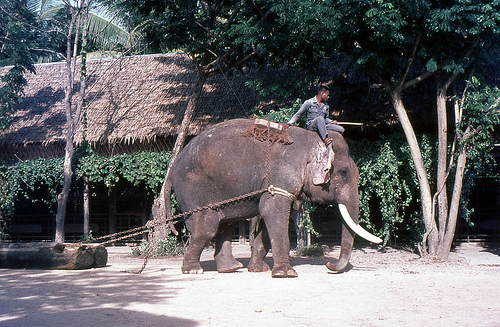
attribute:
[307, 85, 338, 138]
man — sitting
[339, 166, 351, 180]
eyes — open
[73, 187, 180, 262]
chain — Brown 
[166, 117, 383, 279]
elephant — walking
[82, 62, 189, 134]
roof — thatched 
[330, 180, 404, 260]
tusks — big 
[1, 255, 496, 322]
road — dirt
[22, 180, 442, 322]
road — dirt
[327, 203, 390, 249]
tusk — white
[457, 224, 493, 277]
path — dirt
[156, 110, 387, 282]
elephant — brown